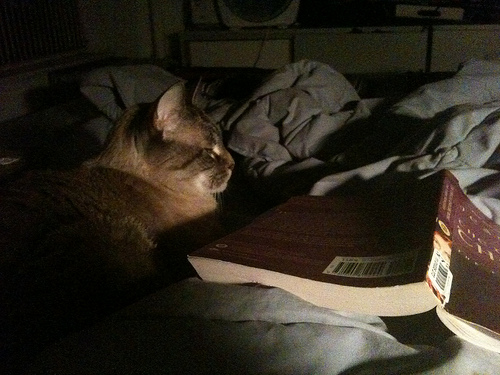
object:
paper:
[183, 254, 439, 318]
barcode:
[321, 246, 456, 306]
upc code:
[319, 250, 418, 280]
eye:
[201, 131, 229, 162]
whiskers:
[198, 178, 225, 215]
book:
[179, 166, 499, 357]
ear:
[154, 79, 189, 144]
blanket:
[233, 31, 494, 171]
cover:
[188, 301, 321, 362]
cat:
[1, 75, 235, 372]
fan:
[215, 0, 298, 33]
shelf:
[179, 21, 497, 74]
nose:
[220, 148, 237, 170]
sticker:
[429, 211, 455, 240]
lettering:
[396, 179, 500, 283]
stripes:
[62, 166, 186, 260]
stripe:
[170, 138, 231, 189]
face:
[167, 110, 243, 194]